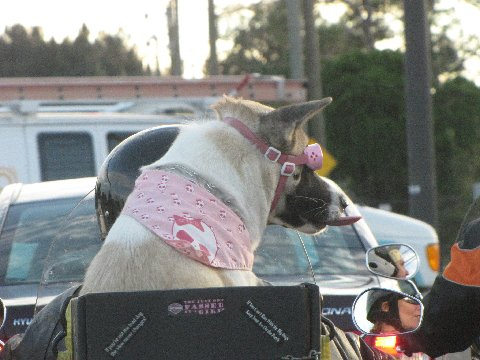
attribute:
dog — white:
[75, 94, 360, 360]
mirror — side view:
[351, 288, 423, 335]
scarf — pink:
[121, 170, 254, 271]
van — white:
[0, 76, 307, 195]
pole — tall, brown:
[405, 1, 438, 241]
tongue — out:
[331, 216, 361, 225]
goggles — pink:
[211, 118, 323, 223]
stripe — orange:
[444, 244, 480, 286]